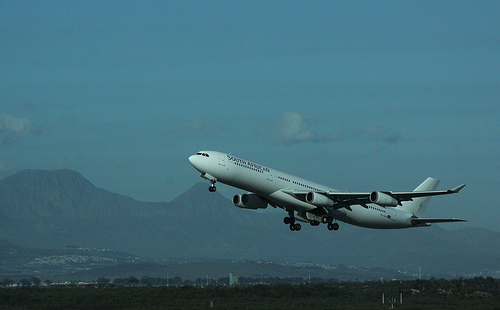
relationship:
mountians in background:
[0, 149, 283, 286] [4, 166, 494, 291]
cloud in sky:
[274, 108, 330, 157] [17, 1, 487, 113]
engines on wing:
[301, 185, 393, 213] [297, 178, 494, 210]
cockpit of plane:
[174, 140, 226, 175] [160, 132, 473, 242]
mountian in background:
[1, 140, 157, 223] [4, 166, 494, 291]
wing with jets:
[297, 178, 494, 210] [301, 185, 393, 213]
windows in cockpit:
[194, 150, 207, 158] [174, 140, 226, 175]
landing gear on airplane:
[257, 203, 349, 248] [160, 132, 473, 242]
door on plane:
[210, 151, 229, 177] [160, 132, 473, 242]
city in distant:
[0, 240, 478, 291] [0, 251, 499, 307]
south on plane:
[222, 152, 248, 164] [160, 132, 473, 242]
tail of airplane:
[412, 166, 448, 195] [160, 132, 473, 242]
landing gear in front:
[208, 171, 216, 200] [162, 108, 249, 200]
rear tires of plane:
[257, 221, 342, 249] [160, 132, 473, 242]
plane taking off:
[160, 132, 473, 242] [129, 135, 482, 300]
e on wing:
[275, 206, 345, 241] [297, 178, 494, 210]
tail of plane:
[412, 166, 448, 195] [160, 132, 473, 242]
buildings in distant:
[0, 240, 478, 291] [0, 251, 499, 307]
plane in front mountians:
[160, 132, 473, 242] [0, 149, 283, 286]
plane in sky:
[160, 132, 473, 242] [17, 1, 487, 113]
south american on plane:
[219, 142, 274, 175] [160, 132, 473, 242]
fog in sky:
[1, 1, 495, 234] [17, 1, 487, 113]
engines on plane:
[301, 185, 393, 213] [160, 132, 473, 242]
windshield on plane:
[187, 140, 220, 161] [160, 132, 473, 242]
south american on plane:
[227, 155, 270, 172] [160, 132, 473, 242]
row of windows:
[220, 163, 328, 191] [223, 161, 402, 222]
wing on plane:
[297, 178, 494, 210] [160, 132, 473, 242]